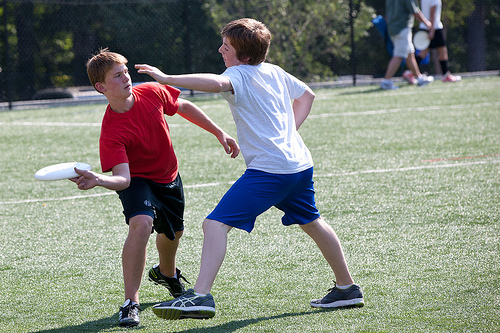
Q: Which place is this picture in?
A: It is at the field.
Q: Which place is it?
A: It is a field.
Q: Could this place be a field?
A: Yes, it is a field.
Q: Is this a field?
A: Yes, it is a field.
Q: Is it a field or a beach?
A: It is a field.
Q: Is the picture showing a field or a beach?
A: It is showing a field.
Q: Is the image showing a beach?
A: No, the picture is showing a field.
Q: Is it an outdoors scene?
A: Yes, it is outdoors.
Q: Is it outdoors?
A: Yes, it is outdoors.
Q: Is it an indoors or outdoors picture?
A: It is outdoors.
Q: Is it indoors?
A: No, it is outdoors.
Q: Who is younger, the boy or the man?
A: The boy is younger than the man.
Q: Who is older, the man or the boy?
A: The man is older than the boy.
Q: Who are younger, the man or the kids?
A: The kids are younger than the man.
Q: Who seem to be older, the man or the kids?
A: The man are older than the kids.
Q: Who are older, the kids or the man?
A: The man are older than the kids.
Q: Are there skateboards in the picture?
A: No, there are no skateboards.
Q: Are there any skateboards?
A: No, there are no skateboards.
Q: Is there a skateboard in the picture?
A: No, there are no skateboards.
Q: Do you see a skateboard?
A: No, there are no skateboards.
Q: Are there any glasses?
A: No, there are no glasses.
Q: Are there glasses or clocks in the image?
A: No, there are no glasses or clocks.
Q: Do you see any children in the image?
A: Yes, there are children.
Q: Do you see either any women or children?
A: Yes, there are children.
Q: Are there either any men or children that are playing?
A: Yes, the children are playing.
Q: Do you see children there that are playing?
A: Yes, there are children that are playing.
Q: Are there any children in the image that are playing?
A: Yes, there are children that are playing.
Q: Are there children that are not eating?
A: Yes, there are children that are playing.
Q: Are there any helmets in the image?
A: No, there are no helmets.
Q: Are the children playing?
A: Yes, the children are playing.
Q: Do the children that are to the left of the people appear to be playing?
A: Yes, the children are playing.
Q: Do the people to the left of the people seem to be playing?
A: Yes, the children are playing.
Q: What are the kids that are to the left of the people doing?
A: The kids are playing.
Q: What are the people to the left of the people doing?
A: The kids are playing.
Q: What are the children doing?
A: The kids are playing.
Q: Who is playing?
A: The children are playing.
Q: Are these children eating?
A: No, the children are playing.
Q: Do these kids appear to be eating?
A: No, the kids are playing.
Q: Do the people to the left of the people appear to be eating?
A: No, the kids are playing.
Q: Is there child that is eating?
A: No, there are children but they are playing.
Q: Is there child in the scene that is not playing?
A: No, there are children but they are playing.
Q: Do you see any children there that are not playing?
A: No, there are children but they are playing.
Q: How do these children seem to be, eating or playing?
A: The children are playing.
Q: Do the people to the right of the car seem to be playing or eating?
A: The children are playing.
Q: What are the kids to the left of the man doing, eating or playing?
A: The children are playing.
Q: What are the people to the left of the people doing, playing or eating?
A: The children are playing.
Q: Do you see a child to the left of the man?
A: Yes, there are children to the left of the man.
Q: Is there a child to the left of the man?
A: Yes, there are children to the left of the man.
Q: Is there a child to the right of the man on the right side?
A: No, the children are to the left of the man.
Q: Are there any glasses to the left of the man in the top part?
A: No, there are children to the left of the man.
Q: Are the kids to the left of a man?
A: Yes, the kids are to the left of a man.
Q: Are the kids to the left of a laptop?
A: No, the kids are to the left of a man.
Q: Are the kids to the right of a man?
A: No, the kids are to the left of a man.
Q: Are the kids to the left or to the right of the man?
A: The kids are to the left of the man.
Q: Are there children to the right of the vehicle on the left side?
A: Yes, there are children to the right of the car.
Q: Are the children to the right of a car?
A: Yes, the children are to the right of a car.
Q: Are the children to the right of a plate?
A: No, the children are to the right of a car.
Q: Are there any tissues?
A: No, there are no tissues.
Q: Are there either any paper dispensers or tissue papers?
A: No, there are no tissue papers or paper dispensers.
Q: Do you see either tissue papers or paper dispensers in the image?
A: No, there are no tissue papers or paper dispensers.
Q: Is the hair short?
A: Yes, the hair is short.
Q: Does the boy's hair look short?
A: Yes, the hair is short.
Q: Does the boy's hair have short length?
A: Yes, the hair is short.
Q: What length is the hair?
A: The hair is short.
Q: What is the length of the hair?
A: The hair is short.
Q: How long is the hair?
A: The hair is short.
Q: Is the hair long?
A: No, the hair is short.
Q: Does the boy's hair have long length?
A: No, the hair is short.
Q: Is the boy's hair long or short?
A: The hair is short.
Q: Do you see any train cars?
A: No, there are no train cars.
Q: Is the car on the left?
A: Yes, the car is on the left of the image.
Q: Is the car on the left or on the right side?
A: The car is on the left of the image.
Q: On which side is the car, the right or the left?
A: The car is on the left of the image.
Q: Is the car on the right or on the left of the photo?
A: The car is on the left of the image.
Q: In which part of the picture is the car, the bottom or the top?
A: The car is in the top of the image.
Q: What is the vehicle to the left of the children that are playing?
A: The vehicle is a car.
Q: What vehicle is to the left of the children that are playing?
A: The vehicle is a car.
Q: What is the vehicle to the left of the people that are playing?
A: The vehicle is a car.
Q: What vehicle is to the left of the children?
A: The vehicle is a car.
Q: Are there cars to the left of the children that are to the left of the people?
A: Yes, there is a car to the left of the children.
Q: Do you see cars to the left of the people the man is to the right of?
A: Yes, there is a car to the left of the children.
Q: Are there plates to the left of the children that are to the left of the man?
A: No, there is a car to the left of the kids.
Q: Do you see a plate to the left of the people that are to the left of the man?
A: No, there is a car to the left of the kids.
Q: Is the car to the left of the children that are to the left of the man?
A: Yes, the car is to the left of the kids.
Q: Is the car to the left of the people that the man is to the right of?
A: Yes, the car is to the left of the kids.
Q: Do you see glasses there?
A: No, there are no glasses.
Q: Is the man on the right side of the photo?
A: Yes, the man is on the right of the image.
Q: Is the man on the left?
A: No, the man is on the right of the image.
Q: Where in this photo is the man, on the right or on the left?
A: The man is on the right of the image.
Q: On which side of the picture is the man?
A: The man is on the right of the image.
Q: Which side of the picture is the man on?
A: The man is on the right of the image.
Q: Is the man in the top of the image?
A: Yes, the man is in the top of the image.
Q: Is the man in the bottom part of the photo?
A: No, the man is in the top of the image.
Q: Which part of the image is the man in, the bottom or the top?
A: The man is in the top of the image.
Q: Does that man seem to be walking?
A: Yes, the man is walking.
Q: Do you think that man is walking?
A: Yes, the man is walking.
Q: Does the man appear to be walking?
A: Yes, the man is walking.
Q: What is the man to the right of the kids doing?
A: The man is walking.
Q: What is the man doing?
A: The man is walking.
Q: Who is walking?
A: The man is walking.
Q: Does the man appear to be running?
A: No, the man is walking.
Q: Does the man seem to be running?
A: No, the man is walking.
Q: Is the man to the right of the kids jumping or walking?
A: The man is walking.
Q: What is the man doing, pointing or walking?
A: The man is walking.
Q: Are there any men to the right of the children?
A: Yes, there is a man to the right of the children.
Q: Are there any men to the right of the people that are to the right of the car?
A: Yes, there is a man to the right of the children.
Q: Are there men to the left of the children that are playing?
A: No, the man is to the right of the children.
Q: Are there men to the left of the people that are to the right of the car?
A: No, the man is to the right of the children.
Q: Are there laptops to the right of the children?
A: No, there is a man to the right of the children.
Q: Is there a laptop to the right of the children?
A: No, there is a man to the right of the children.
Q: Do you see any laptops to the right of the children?
A: No, there is a man to the right of the children.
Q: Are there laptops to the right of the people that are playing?
A: No, there is a man to the right of the children.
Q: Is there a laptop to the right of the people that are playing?
A: No, there is a man to the right of the children.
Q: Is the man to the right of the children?
A: Yes, the man is to the right of the children.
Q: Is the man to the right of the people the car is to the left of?
A: Yes, the man is to the right of the children.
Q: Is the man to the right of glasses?
A: No, the man is to the right of the children.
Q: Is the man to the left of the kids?
A: No, the man is to the right of the kids.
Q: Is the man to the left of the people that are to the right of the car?
A: No, the man is to the right of the kids.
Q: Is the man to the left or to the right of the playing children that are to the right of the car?
A: The man is to the right of the kids.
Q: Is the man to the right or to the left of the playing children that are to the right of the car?
A: The man is to the right of the kids.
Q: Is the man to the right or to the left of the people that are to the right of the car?
A: The man is to the right of the kids.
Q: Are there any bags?
A: No, there are no bags.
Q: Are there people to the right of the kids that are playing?
A: Yes, there are people to the right of the children.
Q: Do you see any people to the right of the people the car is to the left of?
A: Yes, there are people to the right of the children.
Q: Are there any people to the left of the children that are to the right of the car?
A: No, the people are to the right of the children.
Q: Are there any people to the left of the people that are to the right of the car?
A: No, the people are to the right of the children.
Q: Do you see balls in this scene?
A: No, there are no balls.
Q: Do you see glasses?
A: No, there are no glasses.